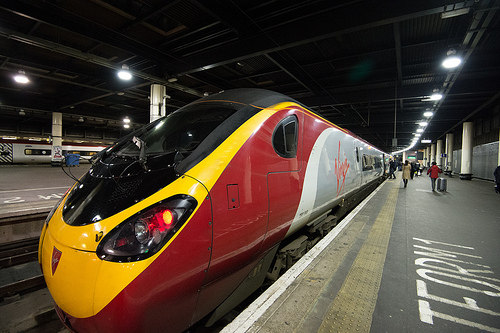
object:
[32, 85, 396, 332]
train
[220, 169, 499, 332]
platform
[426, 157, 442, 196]
person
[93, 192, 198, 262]
headlight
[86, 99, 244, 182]
windshield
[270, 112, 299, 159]
side window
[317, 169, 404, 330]
line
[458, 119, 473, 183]
pillar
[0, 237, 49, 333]
tracks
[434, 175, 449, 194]
luggage bag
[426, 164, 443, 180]
jacket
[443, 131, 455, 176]
pillar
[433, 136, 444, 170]
pillar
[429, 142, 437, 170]
pillar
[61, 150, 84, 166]
container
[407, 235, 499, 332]
writing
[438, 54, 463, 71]
ceiling light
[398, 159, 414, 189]
person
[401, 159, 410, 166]
hair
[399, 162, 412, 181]
coat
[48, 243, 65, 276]
logo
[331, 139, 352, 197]
writing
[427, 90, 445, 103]
light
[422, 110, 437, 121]
light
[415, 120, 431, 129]
light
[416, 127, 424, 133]
light